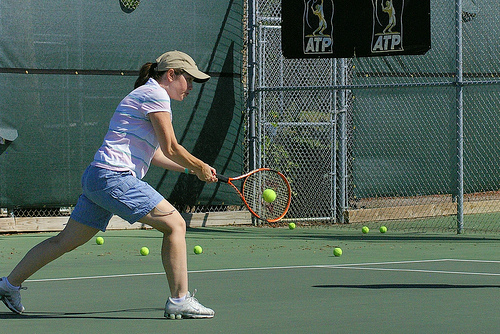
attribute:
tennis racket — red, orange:
[213, 166, 293, 223]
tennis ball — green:
[264, 188, 276, 202]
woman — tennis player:
[0, 50, 219, 320]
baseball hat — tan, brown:
[153, 50, 212, 85]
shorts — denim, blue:
[69, 164, 166, 233]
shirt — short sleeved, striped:
[90, 76, 173, 180]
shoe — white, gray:
[164, 287, 215, 319]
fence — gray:
[247, 0, 499, 235]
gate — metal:
[258, 22, 338, 224]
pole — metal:
[454, 0, 464, 235]